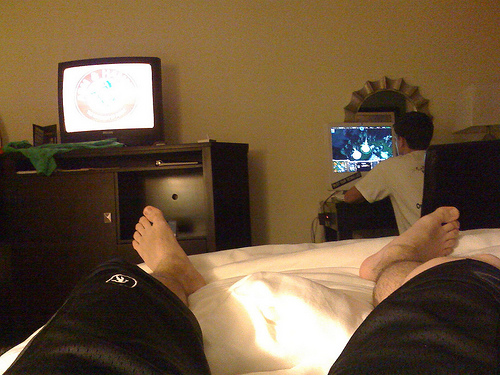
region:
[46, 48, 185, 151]
Television sitting on top of dresser.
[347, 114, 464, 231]
Young boy sitting at desk looking at computer.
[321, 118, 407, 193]
Computer screen on PC.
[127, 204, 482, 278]
Bare feet of man laying on bed.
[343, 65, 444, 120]
Top part of mirror hanging on wall.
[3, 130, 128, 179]
Green cloth laying on dresser.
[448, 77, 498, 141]
Shade portion of lamp.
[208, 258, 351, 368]
White crumpled sheet on bed.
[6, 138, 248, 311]
A brown dresser with missing door.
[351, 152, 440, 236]
Young boy dressed in white t-shirt.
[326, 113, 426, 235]
boy sitting at computer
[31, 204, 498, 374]
legs and feet of someone watching tv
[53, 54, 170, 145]
television on top of cabinet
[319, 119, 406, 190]
computer screen which boy is watching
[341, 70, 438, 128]
wall mirror behind computer monitor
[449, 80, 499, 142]
table lamp beside computer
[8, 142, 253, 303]
cabinet on which tv is sitting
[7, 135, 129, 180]
green cloth on cabinet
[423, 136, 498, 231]
back of chair in which boy is sitting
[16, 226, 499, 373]
bed on which person watching tv is sitting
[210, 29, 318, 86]
solid yellow walls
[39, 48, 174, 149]
large television on top of drawer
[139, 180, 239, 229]
open section in dark brown drawer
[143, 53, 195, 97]
black edge of television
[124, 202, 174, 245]
toes on man's foot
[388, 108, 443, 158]
man's short hair cut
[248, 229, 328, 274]
edge of white sheet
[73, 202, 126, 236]
small spot on chesnut drawer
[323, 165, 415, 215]
man's short sleeve white shirt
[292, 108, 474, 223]
man playing game at console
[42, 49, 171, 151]
One older style Television.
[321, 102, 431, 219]
Male sitting in front of a computer.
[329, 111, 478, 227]
Boy sitting in a black chair.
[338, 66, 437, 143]
Round mirror hanging on the wall.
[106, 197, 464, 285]
Two human feet without socks on.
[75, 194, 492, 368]
Man's legs resting on the bed.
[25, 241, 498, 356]
Man laying down with black shorts on.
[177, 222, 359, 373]
White bedding on the bed.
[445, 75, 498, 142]
White square lampshade.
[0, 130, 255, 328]
Brown, wood entertainment center.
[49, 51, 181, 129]
A CRT television set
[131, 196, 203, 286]
A mans foot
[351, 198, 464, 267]
A mans right foot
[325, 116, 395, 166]
A computer monitor with game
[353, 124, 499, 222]
A man sitting in a chair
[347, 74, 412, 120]
A mirror hanging on wall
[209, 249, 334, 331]
A white bed sheet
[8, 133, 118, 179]
A green towel on counter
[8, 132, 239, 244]
A counter table with foot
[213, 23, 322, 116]
A white plaster wall